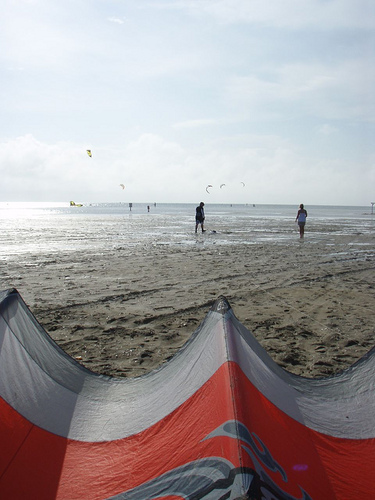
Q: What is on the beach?
A: Strollers and kite fliers.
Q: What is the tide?
A: Low tide.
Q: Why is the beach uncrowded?
A: Day is ending.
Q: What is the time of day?
A: Late afternoon.